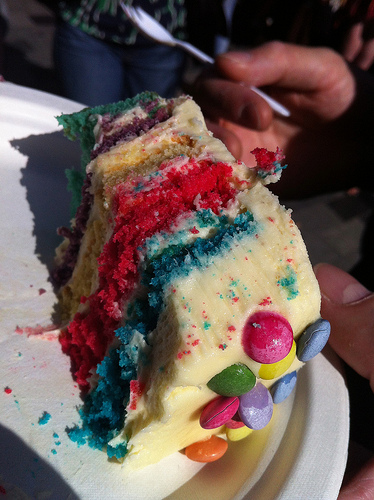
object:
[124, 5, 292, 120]
spork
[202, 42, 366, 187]
hand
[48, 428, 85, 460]
crump cake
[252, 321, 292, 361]
candy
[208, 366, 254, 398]
candy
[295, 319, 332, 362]
candy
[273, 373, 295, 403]
candy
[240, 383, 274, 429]
candy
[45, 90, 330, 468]
cake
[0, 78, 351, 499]
plate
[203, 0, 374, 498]
man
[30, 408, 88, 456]
crumbs